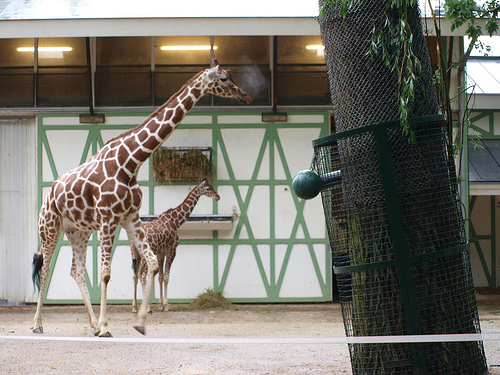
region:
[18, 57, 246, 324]
The giraffe is brown and tan.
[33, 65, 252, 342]
The giraffe is walking.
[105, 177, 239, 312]
The giraffe is standing.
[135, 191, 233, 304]
The giraffe is eating.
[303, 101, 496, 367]
The tree has a net around it.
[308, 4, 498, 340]
The tree trunk is brown.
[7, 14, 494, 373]
They are in a zoo.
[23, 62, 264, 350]
two giraffes standing.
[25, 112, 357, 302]
The wall is white and green.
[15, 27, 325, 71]
The lights are on.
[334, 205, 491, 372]
moss growing on the tree.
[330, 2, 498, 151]
the leaves are green.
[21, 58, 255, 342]
two giraffes are walking.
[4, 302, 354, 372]
the ground is dirt.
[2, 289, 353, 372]
the ground is brown.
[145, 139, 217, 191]
basket on the wall.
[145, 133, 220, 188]
the basket is full.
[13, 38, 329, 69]
the lights are on.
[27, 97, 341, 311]
the wall is white and green.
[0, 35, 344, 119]
windows on the wall.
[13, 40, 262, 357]
adult giraffe standing next to juvenile giraffe on dirt ground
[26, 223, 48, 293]
giraffe tail with black hair at tip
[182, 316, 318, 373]
patch of tan dirt ground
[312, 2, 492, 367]
brown tree trunk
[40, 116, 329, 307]
green and tan side of wall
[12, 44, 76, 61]
white ceiling light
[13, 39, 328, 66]
three white interior white ceiling light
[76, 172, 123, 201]
brown and white spots on giraffe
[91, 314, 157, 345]
grey giraffe hooves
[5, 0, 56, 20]
piece of grey roofing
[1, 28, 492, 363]
Giraffes are in captivity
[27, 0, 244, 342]
Two giraffes in the pen.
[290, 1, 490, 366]
One tree with a cage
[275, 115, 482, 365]
Green cage around tree trunk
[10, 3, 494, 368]
Photo taken during the day.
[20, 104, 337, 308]
White wall with green trim.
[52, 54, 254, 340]
Giraffes are brown and white.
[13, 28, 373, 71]
Flourescent lights inside the building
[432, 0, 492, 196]
Metal roof on the building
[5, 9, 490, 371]
Nobody shown with the giraffes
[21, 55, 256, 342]
two giraffe's are visible.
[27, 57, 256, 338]
giraffes walking on dirt.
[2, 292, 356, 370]
the dirt is brown.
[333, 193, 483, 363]
the moss is green.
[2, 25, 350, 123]
windows on the building.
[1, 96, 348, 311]
the building is white and green.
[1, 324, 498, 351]
the string is white.